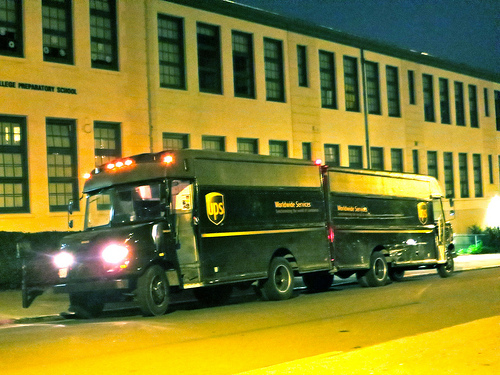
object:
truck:
[51, 148, 455, 320]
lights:
[101, 244, 128, 263]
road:
[0, 267, 500, 375]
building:
[0, 1, 499, 234]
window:
[263, 36, 286, 103]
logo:
[205, 192, 226, 226]